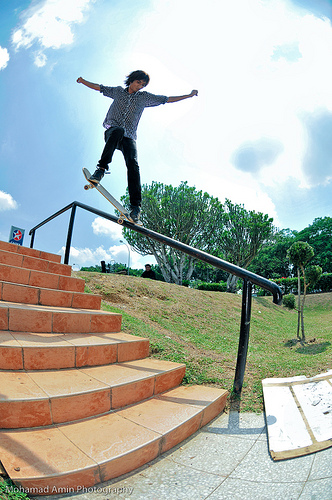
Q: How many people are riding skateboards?
A: One.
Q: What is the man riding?
A: A skateboard.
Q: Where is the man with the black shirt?
A: By the tree.